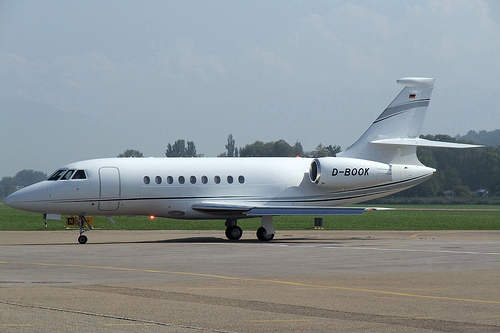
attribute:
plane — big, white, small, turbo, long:
[2, 77, 485, 246]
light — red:
[150, 215, 156, 221]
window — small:
[144, 176, 150, 184]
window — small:
[237, 175, 245, 183]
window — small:
[189, 175, 196, 184]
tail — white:
[337, 78, 484, 167]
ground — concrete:
[1, 228, 497, 332]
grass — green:
[275, 206, 498, 231]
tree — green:
[166, 139, 197, 157]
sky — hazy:
[1, 0, 500, 179]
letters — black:
[329, 165, 373, 178]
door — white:
[98, 167, 119, 213]